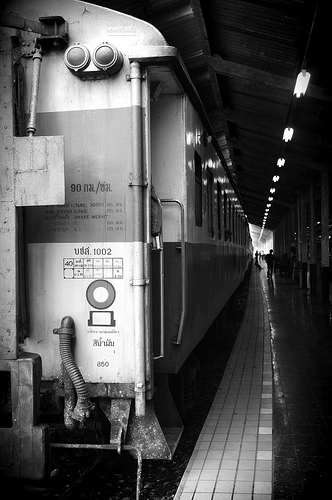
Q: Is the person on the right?
A: Yes, the person is on the right of the image.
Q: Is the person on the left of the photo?
A: No, the person is on the right of the image.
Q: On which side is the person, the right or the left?
A: The person is on the right of the image.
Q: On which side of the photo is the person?
A: The person is on the right of the image.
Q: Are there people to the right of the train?
A: Yes, there is a person to the right of the train.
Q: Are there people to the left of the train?
A: No, the person is to the right of the train.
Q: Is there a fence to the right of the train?
A: No, there is a person to the right of the train.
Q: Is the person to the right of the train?
A: Yes, the person is to the right of the train.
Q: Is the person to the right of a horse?
A: No, the person is to the right of the train.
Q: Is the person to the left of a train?
A: No, the person is to the right of a train.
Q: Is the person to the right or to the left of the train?
A: The person is to the right of the train.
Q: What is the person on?
A: The person is on the platform.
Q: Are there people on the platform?
A: Yes, there is a person on the platform.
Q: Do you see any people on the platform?
A: Yes, there is a person on the platform.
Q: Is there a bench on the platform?
A: No, there is a person on the platform.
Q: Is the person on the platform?
A: Yes, the person is on the platform.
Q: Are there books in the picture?
A: No, there are no books.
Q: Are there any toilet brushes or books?
A: No, there are no books or toilet brushes.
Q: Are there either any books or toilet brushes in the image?
A: No, there are no books or toilet brushes.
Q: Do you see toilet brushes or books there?
A: No, there are no books or toilet brushes.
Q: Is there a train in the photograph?
A: Yes, there is a train.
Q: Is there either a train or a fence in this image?
A: Yes, there is a train.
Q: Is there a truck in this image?
A: No, there are no trucks.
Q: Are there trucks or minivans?
A: No, there are no trucks or minivans.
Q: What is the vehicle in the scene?
A: The vehicle is a train.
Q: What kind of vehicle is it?
A: The vehicle is a train.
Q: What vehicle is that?
A: This is a train.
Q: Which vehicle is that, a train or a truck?
A: This is a train.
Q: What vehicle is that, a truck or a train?
A: This is a train.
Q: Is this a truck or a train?
A: This is a train.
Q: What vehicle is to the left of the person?
A: The vehicle is a train.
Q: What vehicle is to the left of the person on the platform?
A: The vehicle is a train.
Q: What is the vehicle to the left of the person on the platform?
A: The vehicle is a train.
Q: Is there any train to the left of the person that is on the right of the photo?
A: Yes, there is a train to the left of the person.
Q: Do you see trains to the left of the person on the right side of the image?
A: Yes, there is a train to the left of the person.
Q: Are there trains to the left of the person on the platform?
A: Yes, there is a train to the left of the person.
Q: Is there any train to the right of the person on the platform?
A: No, the train is to the left of the person.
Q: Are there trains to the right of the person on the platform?
A: No, the train is to the left of the person.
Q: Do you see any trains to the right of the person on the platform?
A: No, the train is to the left of the person.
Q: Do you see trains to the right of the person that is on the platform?
A: No, the train is to the left of the person.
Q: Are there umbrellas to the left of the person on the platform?
A: No, there is a train to the left of the person.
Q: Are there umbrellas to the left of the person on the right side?
A: No, there is a train to the left of the person.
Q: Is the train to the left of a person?
A: Yes, the train is to the left of a person.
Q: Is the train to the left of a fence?
A: No, the train is to the left of a person.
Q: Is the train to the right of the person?
A: No, the train is to the left of the person.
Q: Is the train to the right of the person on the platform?
A: No, the train is to the left of the person.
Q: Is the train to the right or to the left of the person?
A: The train is to the left of the person.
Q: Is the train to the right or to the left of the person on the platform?
A: The train is to the left of the person.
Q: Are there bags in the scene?
A: No, there are no bags.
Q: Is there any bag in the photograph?
A: No, there are no bags.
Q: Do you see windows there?
A: Yes, there is a window.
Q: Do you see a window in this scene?
A: Yes, there is a window.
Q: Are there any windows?
A: Yes, there is a window.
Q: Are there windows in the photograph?
A: Yes, there is a window.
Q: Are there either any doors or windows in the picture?
A: Yes, there is a window.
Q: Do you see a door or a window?
A: Yes, there is a window.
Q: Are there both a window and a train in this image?
A: Yes, there are both a window and a train.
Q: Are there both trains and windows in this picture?
A: Yes, there are both a window and a train.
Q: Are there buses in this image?
A: No, there are no buses.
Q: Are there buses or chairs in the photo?
A: No, there are no buses or chairs.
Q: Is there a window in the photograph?
A: Yes, there is a window.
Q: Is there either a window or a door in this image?
A: Yes, there is a window.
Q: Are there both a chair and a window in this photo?
A: No, there is a window but no chairs.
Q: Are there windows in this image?
A: Yes, there is a window.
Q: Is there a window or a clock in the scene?
A: Yes, there is a window.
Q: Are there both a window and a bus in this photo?
A: No, there is a window but no buses.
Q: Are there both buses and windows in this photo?
A: No, there is a window but no buses.